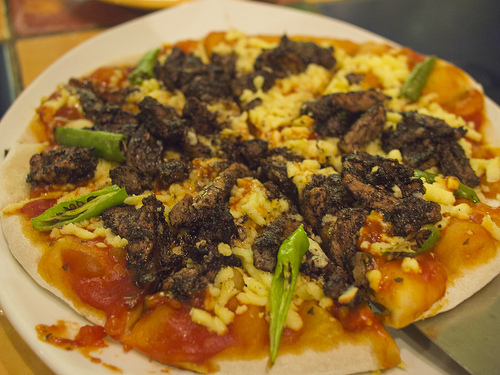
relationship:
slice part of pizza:
[206, 17, 356, 177] [0, 28, 499, 373]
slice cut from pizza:
[206, 17, 356, 177] [0, 28, 499, 373]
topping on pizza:
[116, 176, 248, 306] [0, 28, 499, 373]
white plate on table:
[0, 0, 497, 374] [0, 25, 497, 374]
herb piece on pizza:
[391, 262, 408, 286] [0, 28, 499, 373]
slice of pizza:
[206, 17, 356, 177] [0, 28, 499, 373]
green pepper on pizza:
[259, 219, 310, 361] [0, 28, 499, 373]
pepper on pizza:
[403, 52, 438, 103] [0, 28, 499, 373]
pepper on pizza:
[411, 169, 478, 203] [0, 28, 499, 373]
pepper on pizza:
[414, 225, 441, 252] [0, 28, 499, 373]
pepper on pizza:
[32, 184, 125, 231] [0, 28, 499, 373]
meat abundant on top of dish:
[61, 61, 438, 318] [3, 2, 495, 371]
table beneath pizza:
[413, 324, 498, 354] [0, 28, 499, 373]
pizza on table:
[0, 28, 499, 373] [0, 11, 498, 375]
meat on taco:
[346, 145, 394, 192] [26, 90, 466, 347]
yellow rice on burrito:
[187, 266, 247, 342] [12, 40, 499, 352]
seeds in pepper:
[75, 201, 83, 207] [32, 184, 125, 231]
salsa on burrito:
[154, 306, 219, 346] [80, 40, 447, 353]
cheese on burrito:
[204, 241, 269, 308] [80, 40, 447, 353]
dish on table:
[3, 2, 495, 371] [0, 25, 497, 374]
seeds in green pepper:
[75, 201, 83, 207] [259, 219, 310, 361]